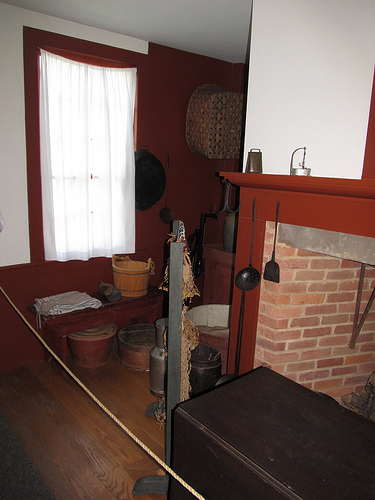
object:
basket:
[112, 257, 154, 298]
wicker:
[185, 84, 243, 160]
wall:
[0, 0, 244, 376]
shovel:
[262, 200, 281, 284]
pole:
[132, 220, 182, 496]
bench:
[34, 283, 163, 374]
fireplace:
[253, 219, 374, 400]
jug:
[149, 316, 166, 397]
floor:
[1, 361, 177, 500]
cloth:
[40, 49, 138, 261]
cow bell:
[289, 148, 311, 176]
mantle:
[278, 223, 375, 267]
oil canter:
[244, 148, 262, 174]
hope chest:
[167, 365, 375, 500]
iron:
[267, 264, 275, 276]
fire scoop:
[235, 198, 261, 291]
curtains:
[37, 45, 138, 260]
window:
[39, 52, 139, 258]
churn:
[150, 317, 173, 393]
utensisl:
[222, 198, 340, 316]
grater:
[221, 171, 375, 197]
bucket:
[110, 255, 153, 298]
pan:
[122, 145, 167, 211]